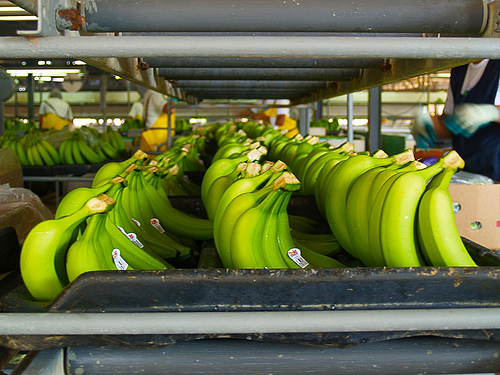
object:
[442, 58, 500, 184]
uniform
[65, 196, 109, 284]
banana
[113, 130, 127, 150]
banana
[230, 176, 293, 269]
banana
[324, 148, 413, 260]
banana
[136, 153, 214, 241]
banana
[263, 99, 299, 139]
apron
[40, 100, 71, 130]
apron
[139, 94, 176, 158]
apron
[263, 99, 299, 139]
worker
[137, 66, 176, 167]
worker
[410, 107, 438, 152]
gloves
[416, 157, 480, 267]
banana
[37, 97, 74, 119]
upper body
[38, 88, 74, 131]
person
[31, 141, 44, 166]
banana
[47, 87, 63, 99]
hairnet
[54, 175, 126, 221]
banana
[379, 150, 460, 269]
banana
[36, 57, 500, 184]
group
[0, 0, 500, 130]
building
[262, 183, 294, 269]
banana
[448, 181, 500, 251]
box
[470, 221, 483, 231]
bolts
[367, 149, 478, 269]
banana bunch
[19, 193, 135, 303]
banana bunch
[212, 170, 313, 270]
banana bunch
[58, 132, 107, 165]
banana bunch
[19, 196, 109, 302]
banana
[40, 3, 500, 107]
equipment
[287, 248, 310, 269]
emblem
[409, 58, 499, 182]
person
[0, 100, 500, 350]
assembly line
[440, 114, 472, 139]
fingertips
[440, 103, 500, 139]
gloves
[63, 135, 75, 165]
banana